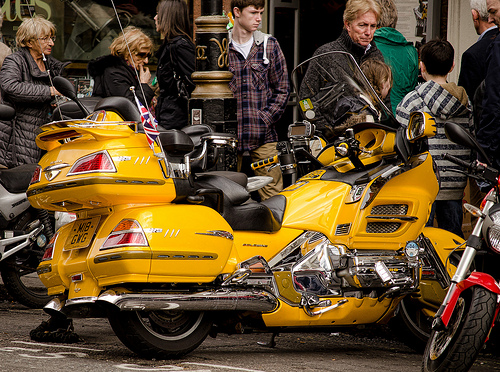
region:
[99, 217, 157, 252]
Rear tail light on a yellow motorcycle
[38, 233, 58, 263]
Rear tail light on a yellow motorcycle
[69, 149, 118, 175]
Rear tail light on a yellow motorcycle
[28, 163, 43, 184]
Rear tail light on a yellow motorcycle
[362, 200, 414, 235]
Side vent of a yellow motorcycle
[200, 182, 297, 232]
Black leather seat of a yellow motorcycle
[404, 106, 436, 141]
Side view mirror of a yellow motorcycle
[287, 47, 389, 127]
Front windshield of a yellow motorcycle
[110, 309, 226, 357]
Rear wheel of a yellow motorcycle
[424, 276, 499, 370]
Front wheel of a red motorcycle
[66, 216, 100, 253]
license plate on bike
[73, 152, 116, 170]
red brake light on bike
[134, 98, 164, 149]
uk flag hanging from bike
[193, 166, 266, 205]
seat on the yellow bike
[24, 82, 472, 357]
yellow bike in street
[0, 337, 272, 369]
white paint in the street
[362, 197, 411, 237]
vents on side of bike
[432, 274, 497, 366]
front tire on red bike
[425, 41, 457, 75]
the boy's black hair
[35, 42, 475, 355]
Two seater yellow motorcycle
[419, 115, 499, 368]
Red frame motorcycle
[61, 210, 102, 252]
Yellow license plate with black letters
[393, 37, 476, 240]
Boy in a sweatshirt with black stripes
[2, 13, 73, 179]
Old woman in a black coat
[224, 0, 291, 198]
Man in a plaid sweatshirt and khaki pants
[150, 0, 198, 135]
Woman in a black coat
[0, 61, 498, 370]
Motorcycles parked on a curb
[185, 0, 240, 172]
Black and gold column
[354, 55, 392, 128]
Girl with braided hair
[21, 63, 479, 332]
yellow motorcycle in parking space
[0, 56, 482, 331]
yellow motorcycle in parking space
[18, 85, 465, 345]
yellow motorcycle in parking space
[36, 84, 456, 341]
yellow motorcycle in parking space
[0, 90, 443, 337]
yellow motorcycle in parking space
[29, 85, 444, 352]
yellow motorcycle in parking space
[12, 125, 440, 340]
yellow motorcycle in parking space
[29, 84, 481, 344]
yellow motorcycle in parking space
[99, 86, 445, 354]
yellow motorcycle in parking space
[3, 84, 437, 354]
yellow motorcycle in parking space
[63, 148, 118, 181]
The bike has a red light.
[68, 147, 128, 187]
The bikes light is off.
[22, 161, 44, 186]
The bike has a red light.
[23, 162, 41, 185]
The bikes light is off.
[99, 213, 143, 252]
The bike has a red light.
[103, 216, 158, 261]
The red light is off.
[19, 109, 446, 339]
The bike is yellow.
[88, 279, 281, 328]
The bike has a chrome pipe.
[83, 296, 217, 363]
The bike has a tire.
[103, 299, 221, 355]
The tire is black.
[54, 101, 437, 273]
A large yellow motorcycle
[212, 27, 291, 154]
A boy with a plaid jacket on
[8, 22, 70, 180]
A woman with a black jacket on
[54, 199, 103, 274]
A yellow license plate on the back of a motorcycle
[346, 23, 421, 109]
A woman with a green jacket on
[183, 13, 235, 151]
A black and gold light pole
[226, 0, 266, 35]
person has a head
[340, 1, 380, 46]
person has a head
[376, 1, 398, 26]
person has a head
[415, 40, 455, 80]
person has a head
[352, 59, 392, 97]
person has a head